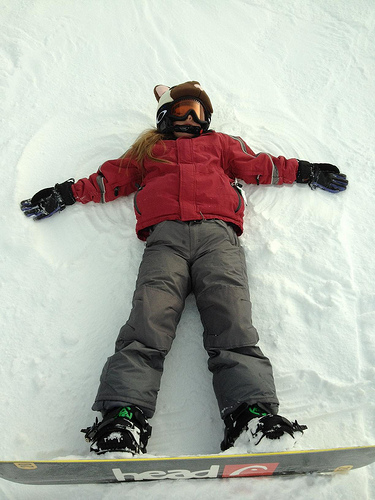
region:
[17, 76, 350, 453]
Snowboarder on the ground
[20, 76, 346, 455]
Snowboarder tracing an angel on the ground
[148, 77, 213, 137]
Helmet worn by the snowboarder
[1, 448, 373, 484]
Black snowboard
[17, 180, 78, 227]
Right glove worn by the person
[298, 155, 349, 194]
Left glove worn by the person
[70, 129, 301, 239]
Red jacket with several stripes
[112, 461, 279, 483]
Logo on the snowboard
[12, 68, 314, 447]
a kid laying down in the snow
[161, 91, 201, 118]
the ski goggles of a kid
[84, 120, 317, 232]
the puffy jacket of a kid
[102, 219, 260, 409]
the puffy ski pants of a child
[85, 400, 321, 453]
a pair of ski boots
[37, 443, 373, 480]
a small black snow board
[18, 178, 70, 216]
a pair of black gloves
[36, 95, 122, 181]
the wing of a snow angel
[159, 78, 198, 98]
a large black snow hat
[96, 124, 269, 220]
person wearing a red snow jacket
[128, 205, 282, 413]
person wearing gray snow pants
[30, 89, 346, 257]
person making a snow angel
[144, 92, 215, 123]
person wearing snow goggles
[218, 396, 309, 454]
boot is black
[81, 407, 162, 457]
boot is black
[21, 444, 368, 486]
person with a snowboard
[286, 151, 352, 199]
black glove with blue finger tips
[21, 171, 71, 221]
black glove with blue finger tips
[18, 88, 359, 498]
person laying down on snow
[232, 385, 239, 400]
This person has a pair of grey snowpants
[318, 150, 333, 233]
This person has a pair of black gloves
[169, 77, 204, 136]
This person has a helmet here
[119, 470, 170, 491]
This snowboard has the word "head"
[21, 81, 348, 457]
Girl lying on the snow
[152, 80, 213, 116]
Hat on the girl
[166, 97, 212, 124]
Goggles on the girl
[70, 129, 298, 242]
Jacket on the girl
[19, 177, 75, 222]
Glove on the girl's right hand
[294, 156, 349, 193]
Glove on the girl's left hand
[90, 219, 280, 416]
Pants on the girl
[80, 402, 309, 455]
Shoes on the girl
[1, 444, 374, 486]
Snowboard on the ground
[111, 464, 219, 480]
Word on the snowboard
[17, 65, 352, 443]
woman laying on snow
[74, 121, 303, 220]
red winter jacket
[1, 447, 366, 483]
black and white snowboard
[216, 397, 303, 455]
snowboard boot on the lady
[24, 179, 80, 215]
snowboard glove on the lady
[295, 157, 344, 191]
snowboard glove on the lady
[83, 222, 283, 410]
snowboard pants on the lady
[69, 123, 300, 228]
snowboard jacket on the lady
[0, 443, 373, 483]
snowboard on the lady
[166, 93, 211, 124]
snowboard goggles on the lady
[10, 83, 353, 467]
lady laying in the cold white snow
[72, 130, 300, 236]
the jacket is dark red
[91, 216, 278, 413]
the pants are gray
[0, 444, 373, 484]
the snowboard is flat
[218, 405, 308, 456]
the snow on the shoe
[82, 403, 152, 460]
the snow on the shoe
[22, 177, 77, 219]
the glove is black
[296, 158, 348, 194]
the glove is black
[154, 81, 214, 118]
the hat has an ear